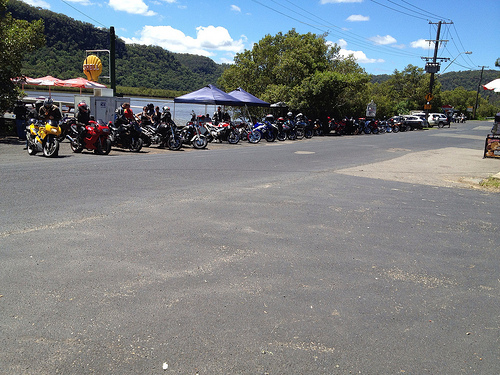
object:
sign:
[79, 54, 103, 78]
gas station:
[23, 82, 107, 102]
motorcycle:
[26, 121, 63, 155]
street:
[64, 148, 409, 220]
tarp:
[170, 86, 244, 106]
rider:
[39, 97, 62, 120]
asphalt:
[374, 188, 417, 216]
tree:
[2, 13, 37, 56]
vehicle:
[401, 114, 427, 128]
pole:
[108, 29, 121, 90]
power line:
[63, 4, 99, 20]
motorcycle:
[72, 129, 112, 153]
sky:
[119, 2, 245, 39]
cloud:
[199, 24, 225, 47]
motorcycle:
[110, 121, 141, 147]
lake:
[175, 97, 200, 116]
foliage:
[47, 44, 68, 57]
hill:
[123, 36, 175, 64]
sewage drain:
[292, 146, 317, 157]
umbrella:
[59, 77, 107, 90]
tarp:
[236, 90, 256, 107]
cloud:
[142, 27, 178, 41]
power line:
[377, 2, 406, 14]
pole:
[434, 22, 443, 65]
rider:
[71, 105, 93, 126]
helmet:
[78, 104, 88, 108]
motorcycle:
[149, 124, 177, 147]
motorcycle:
[181, 126, 201, 143]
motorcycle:
[207, 120, 228, 135]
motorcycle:
[238, 125, 251, 139]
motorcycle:
[278, 129, 288, 141]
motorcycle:
[263, 127, 276, 142]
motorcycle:
[289, 125, 301, 141]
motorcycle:
[305, 127, 315, 139]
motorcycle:
[328, 118, 347, 136]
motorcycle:
[358, 123, 371, 132]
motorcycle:
[379, 123, 387, 133]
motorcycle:
[314, 123, 322, 133]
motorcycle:
[342, 120, 359, 131]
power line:
[326, 27, 344, 37]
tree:
[267, 43, 335, 89]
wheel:
[42, 140, 57, 153]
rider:
[113, 105, 130, 124]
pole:
[87, 48, 111, 54]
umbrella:
[30, 74, 55, 85]